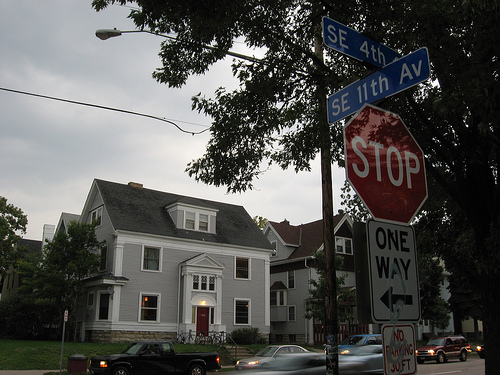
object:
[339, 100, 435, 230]
sign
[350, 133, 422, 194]
stop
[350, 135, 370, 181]
s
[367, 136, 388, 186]
t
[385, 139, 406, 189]
o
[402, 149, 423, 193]
p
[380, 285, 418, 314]
arrow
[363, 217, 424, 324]
sign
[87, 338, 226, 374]
truck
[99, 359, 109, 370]
headlight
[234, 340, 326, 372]
car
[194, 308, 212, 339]
door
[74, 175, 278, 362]
house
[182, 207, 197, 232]
window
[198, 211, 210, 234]
window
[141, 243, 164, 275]
window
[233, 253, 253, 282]
window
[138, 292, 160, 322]
window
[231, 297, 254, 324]
window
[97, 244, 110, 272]
window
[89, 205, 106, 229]
window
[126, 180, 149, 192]
chimney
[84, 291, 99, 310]
window